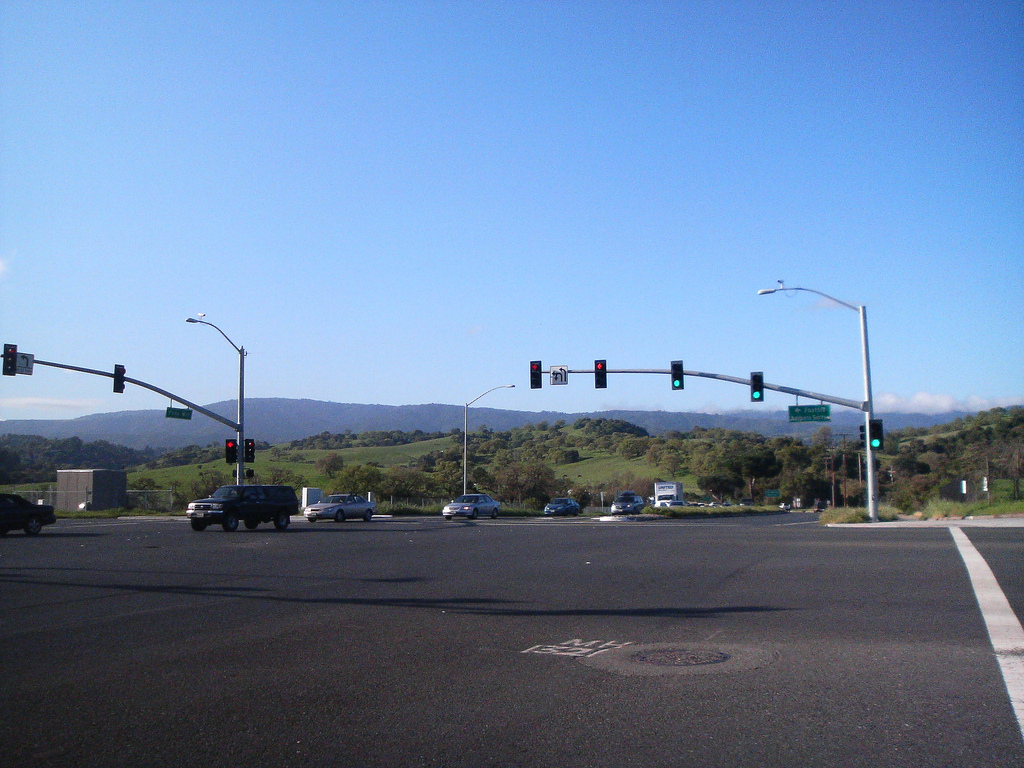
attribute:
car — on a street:
[302, 489, 376, 526]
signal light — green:
[661, 360, 687, 389]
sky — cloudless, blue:
[2, 1, 992, 416]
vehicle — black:
[164, 469, 299, 543]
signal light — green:
[734, 359, 776, 409]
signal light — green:
[857, 404, 894, 463]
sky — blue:
[248, 89, 447, 230]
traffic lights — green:
[656, 351, 695, 397]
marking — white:
[548, 616, 799, 722]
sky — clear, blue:
[306, 68, 756, 311]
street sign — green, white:
[771, 391, 851, 435]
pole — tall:
[751, 264, 922, 571]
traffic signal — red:
[583, 353, 650, 386]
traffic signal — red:
[520, 359, 549, 392]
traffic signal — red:
[216, 437, 242, 453]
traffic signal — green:
[667, 359, 698, 403]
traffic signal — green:
[745, 363, 776, 407]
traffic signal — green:
[862, 407, 884, 457]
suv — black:
[160, 476, 281, 535]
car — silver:
[281, 465, 435, 548]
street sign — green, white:
[765, 379, 845, 431]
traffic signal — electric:
[864, 407, 895, 459]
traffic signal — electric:
[750, 367, 781, 404]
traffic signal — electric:
[664, 347, 688, 387]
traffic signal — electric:
[594, 360, 623, 399]